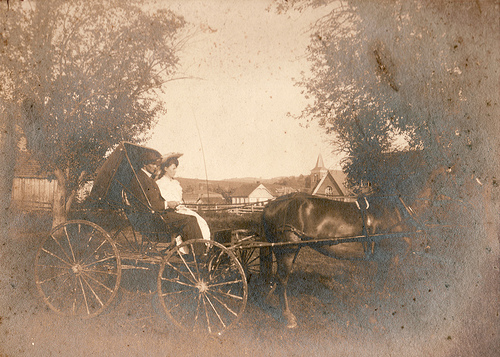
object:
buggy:
[33, 141, 273, 339]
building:
[226, 180, 274, 217]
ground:
[0, 237, 500, 357]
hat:
[161, 153, 184, 169]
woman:
[155, 152, 210, 256]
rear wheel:
[32, 219, 122, 318]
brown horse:
[259, 164, 483, 329]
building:
[295, 149, 360, 202]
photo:
[5, 6, 496, 348]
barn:
[196, 188, 232, 213]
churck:
[304, 152, 346, 199]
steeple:
[310, 152, 328, 189]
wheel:
[156, 238, 248, 341]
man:
[126, 152, 219, 264]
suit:
[123, 169, 206, 256]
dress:
[155, 175, 211, 254]